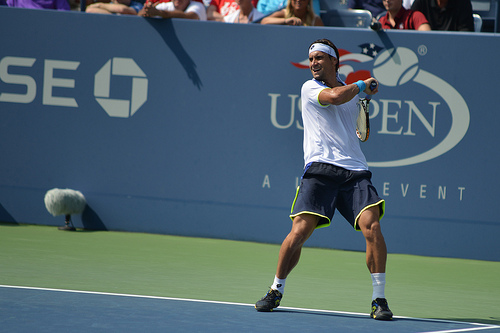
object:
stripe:
[290, 182, 303, 213]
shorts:
[284, 154, 399, 229]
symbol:
[273, 282, 284, 290]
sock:
[267, 271, 291, 296]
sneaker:
[246, 281, 294, 316]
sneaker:
[365, 290, 401, 324]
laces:
[263, 291, 283, 300]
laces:
[376, 297, 387, 309]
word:
[38, 52, 87, 128]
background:
[0, 0, 499, 262]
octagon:
[89, 48, 162, 124]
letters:
[0, 53, 45, 107]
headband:
[302, 39, 340, 59]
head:
[295, 35, 349, 84]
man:
[242, 23, 415, 319]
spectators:
[252, 0, 328, 33]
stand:
[0, 2, 497, 255]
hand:
[362, 75, 381, 96]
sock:
[361, 270, 392, 302]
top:
[285, 37, 387, 171]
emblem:
[307, 43, 322, 53]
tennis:
[0, 0, 499, 333]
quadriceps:
[333, 81, 360, 106]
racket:
[352, 78, 378, 148]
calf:
[274, 239, 307, 280]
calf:
[362, 235, 390, 277]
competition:
[0, 0, 499, 333]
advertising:
[1, 7, 499, 263]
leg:
[271, 216, 320, 287]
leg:
[353, 207, 395, 290]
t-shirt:
[291, 75, 374, 171]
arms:
[317, 77, 382, 124]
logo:
[1, 40, 160, 128]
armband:
[348, 78, 370, 97]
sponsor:
[0, 49, 155, 120]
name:
[244, 29, 491, 210]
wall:
[1, 3, 498, 262]